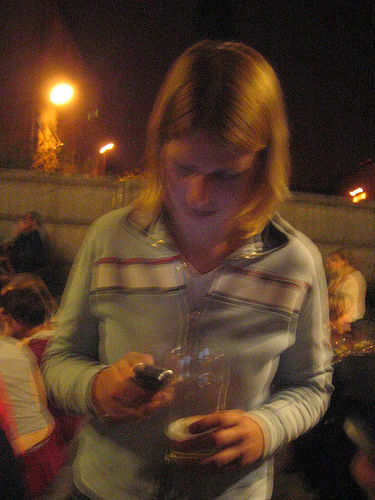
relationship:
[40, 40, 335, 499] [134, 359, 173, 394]
girl using phone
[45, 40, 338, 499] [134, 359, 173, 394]
girl holding phone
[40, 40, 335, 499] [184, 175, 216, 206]
girl has nose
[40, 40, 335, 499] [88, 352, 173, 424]
girl has hand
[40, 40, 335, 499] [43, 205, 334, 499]
girl has jacket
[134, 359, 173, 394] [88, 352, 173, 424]
phone in hand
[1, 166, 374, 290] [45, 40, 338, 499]
fence behind girl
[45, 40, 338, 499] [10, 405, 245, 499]
girl looking down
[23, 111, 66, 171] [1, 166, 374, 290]
tree behind fence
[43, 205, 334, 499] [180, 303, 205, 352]
jacket has zipper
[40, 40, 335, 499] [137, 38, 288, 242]
girl has head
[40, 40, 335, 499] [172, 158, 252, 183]
girl has eyes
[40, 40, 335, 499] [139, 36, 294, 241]
girl has hair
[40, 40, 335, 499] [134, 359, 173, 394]
girl holding phone